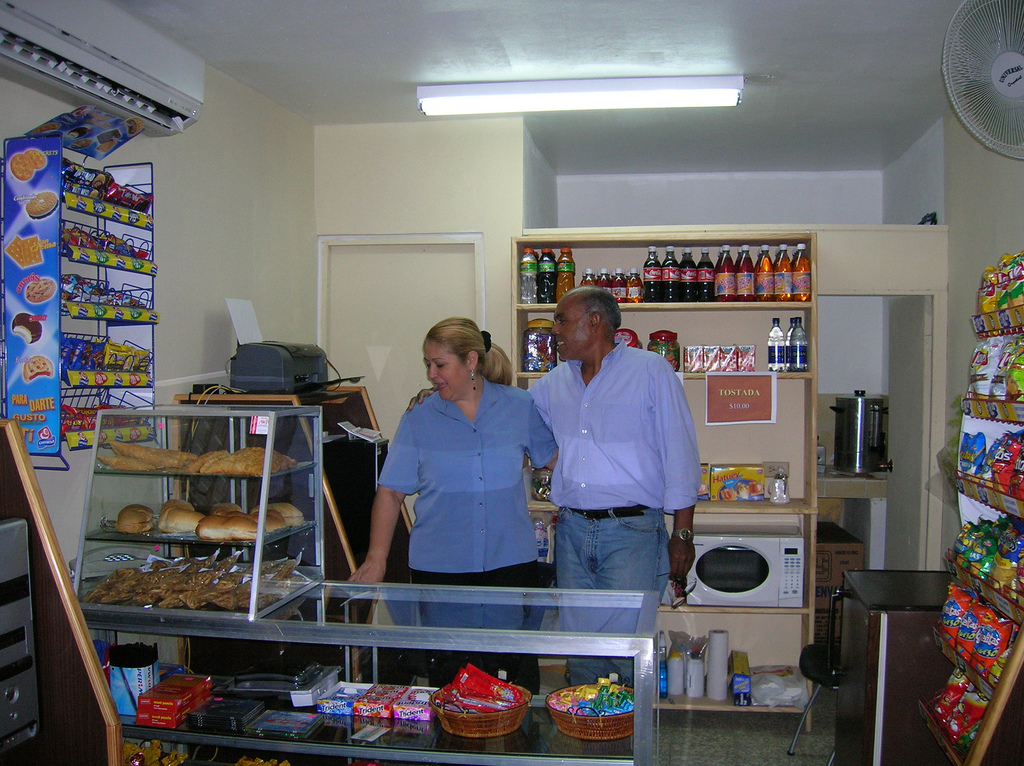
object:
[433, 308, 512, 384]
blonde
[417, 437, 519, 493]
body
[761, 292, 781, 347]
bottle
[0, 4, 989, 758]
store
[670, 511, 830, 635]
microwave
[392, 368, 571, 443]
arm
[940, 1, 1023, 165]
fan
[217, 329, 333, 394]
printer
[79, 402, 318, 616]
food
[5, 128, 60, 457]
pictures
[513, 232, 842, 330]
drinks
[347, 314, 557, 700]
man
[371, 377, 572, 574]
blouse